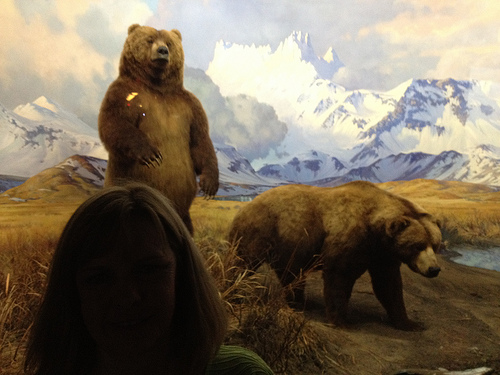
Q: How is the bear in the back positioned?
A: Standing.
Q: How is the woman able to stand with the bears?
A: The bears are fake.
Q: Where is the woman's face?
A: Hidden by shadow.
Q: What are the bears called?
A: Grizzleys.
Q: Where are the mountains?
A: Behind the bears.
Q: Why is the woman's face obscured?
A: Shadows.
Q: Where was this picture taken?
A: A museum.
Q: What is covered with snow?
A: Mountains.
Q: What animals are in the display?
A: Bears.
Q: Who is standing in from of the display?
A: A woman.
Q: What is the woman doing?
A: Taking a pic of herself in front of display.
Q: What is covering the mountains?
A: Snow.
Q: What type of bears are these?
A: Brown bears.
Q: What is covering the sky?
A: White clouds.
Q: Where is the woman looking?
A: At camera.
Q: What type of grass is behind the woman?
A: Tall brown grass.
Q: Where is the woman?
A: In front of the bears.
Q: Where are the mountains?
A: Behind the bears.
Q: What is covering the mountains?
A: Snow.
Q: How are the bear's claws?
A: Long.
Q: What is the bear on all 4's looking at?
A: The ground.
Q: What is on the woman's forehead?
A: Bangs.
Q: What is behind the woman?
A: Fake scene.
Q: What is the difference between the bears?
A: Pose.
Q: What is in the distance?
A: Mountains.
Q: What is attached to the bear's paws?
A: Claws.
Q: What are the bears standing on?
A: Grass.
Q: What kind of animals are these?
A: Brown bears.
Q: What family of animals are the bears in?
A: Mammals.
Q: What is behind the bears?
A: Mountains.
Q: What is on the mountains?
A: Snow.